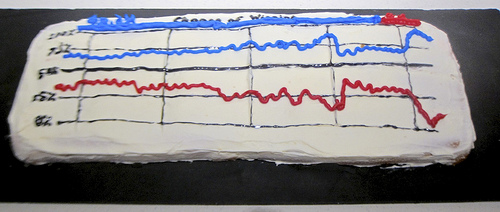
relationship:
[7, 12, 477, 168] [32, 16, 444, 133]
cake has graph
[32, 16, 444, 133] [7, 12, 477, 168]
graph on cake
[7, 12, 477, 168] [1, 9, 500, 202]
cake on table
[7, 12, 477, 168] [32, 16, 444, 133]
cake has design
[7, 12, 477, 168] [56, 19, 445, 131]
cake has lines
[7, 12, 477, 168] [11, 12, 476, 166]
cake has icing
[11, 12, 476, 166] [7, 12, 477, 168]
icing on cake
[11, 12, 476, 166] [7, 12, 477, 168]
frosting on cake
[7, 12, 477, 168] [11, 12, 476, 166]
cake with frosting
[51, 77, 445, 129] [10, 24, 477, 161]
line on cake